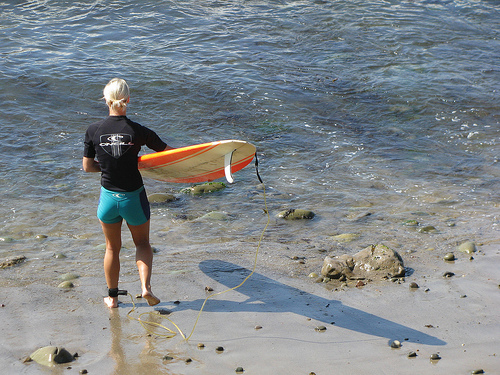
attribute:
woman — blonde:
[82, 78, 176, 309]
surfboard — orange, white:
[137, 140, 257, 184]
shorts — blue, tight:
[96, 186, 151, 225]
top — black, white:
[85, 116, 168, 191]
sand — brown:
[1, 180, 499, 374]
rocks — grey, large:
[1, 182, 498, 373]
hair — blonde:
[100, 79, 131, 113]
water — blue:
[1, 1, 498, 285]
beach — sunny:
[1, 1, 500, 374]